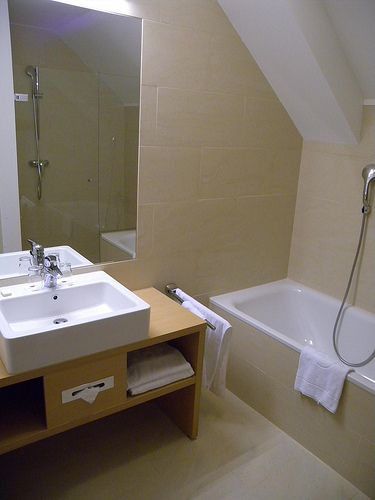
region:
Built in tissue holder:
[61, 375, 115, 403]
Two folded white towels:
[125, 338, 193, 396]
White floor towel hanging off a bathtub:
[294, 344, 355, 412]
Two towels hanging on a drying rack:
[170, 285, 231, 400]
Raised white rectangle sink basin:
[1, 271, 151, 376]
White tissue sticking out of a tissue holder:
[72, 384, 100, 404]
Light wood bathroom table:
[2, 286, 206, 460]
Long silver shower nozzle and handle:
[332, 158, 374, 365]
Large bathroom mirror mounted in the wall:
[0, 0, 145, 280]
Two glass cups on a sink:
[25, 262, 74, 293]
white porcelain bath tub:
[209, 276, 374, 499]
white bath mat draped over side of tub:
[291, 341, 354, 413]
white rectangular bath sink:
[0, 270, 150, 376]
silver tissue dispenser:
[58, 375, 115, 403]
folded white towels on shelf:
[123, 343, 195, 397]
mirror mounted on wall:
[2, 0, 134, 275]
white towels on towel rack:
[175, 287, 231, 401]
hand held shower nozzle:
[332, 163, 374, 367]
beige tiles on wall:
[145, 22, 288, 292]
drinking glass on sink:
[25, 263, 42, 289]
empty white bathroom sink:
[3, 270, 147, 369]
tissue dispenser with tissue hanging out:
[60, 380, 112, 404]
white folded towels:
[126, 345, 189, 393]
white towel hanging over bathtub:
[293, 342, 349, 409]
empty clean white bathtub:
[205, 275, 370, 422]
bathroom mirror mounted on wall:
[2, 12, 140, 258]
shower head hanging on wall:
[360, 165, 371, 205]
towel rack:
[171, 287, 226, 326]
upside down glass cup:
[25, 264, 43, 289]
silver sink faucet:
[41, 253, 63, 287]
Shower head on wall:
[338, 157, 373, 236]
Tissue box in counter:
[52, 373, 121, 406]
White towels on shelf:
[121, 348, 196, 395]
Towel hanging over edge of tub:
[285, 337, 355, 413]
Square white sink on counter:
[1, 263, 152, 376]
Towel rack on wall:
[160, 280, 216, 333]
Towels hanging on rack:
[173, 286, 237, 402]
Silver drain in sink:
[51, 310, 74, 329]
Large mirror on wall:
[0, 13, 140, 275]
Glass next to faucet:
[20, 262, 44, 290]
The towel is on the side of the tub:
[266, 326, 347, 426]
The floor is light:
[174, 457, 252, 498]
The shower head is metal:
[351, 159, 374, 207]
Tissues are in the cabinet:
[45, 373, 134, 418]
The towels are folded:
[131, 363, 220, 401]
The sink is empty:
[21, 282, 110, 354]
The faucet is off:
[31, 238, 85, 287]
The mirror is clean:
[17, 131, 113, 233]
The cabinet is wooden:
[109, 385, 220, 450]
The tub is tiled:
[258, 373, 353, 472]